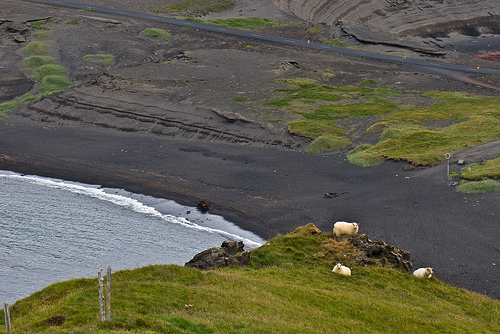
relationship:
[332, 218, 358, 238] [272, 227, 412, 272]
sheep on rocks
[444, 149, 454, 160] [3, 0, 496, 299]
sign in sand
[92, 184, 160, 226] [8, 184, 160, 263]
waves in water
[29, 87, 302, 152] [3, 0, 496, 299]
striations in sand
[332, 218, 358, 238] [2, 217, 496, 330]
sheep on mountain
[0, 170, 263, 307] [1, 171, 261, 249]
water with waves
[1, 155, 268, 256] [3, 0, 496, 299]
shore with sand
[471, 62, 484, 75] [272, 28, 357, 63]
sign on roadway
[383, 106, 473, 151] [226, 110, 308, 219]
grass on ground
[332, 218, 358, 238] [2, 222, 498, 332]
sheep on hillside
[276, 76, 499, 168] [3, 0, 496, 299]
grass patch surrounded by sand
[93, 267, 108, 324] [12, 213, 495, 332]
fenceposts sticking out of ground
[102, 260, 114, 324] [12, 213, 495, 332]
fenceposts sticking out of ground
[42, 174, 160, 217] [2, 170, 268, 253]
foam from wave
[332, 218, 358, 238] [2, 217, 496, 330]
sheep grazing on mountain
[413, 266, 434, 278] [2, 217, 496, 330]
sheep grazing on mountain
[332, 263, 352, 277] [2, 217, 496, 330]
sheep grazing on mountain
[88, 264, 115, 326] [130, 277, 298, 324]
wooden poles sticking out of ground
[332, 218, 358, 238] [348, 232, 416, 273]
sheep standing on outcrop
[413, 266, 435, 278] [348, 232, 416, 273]
sheep standing on outcrop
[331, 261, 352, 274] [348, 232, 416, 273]
sheep standing on outcrop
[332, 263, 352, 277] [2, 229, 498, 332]
sheep lying on ground